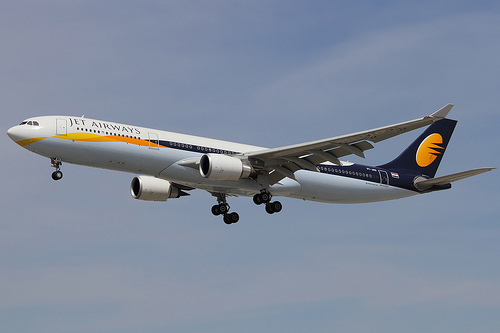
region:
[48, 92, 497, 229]
white, yellow and blue jet airplane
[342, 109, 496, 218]
blue and yellow tail fin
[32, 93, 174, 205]
jet airways airplane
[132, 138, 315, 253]
landing gear coming down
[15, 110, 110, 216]
cockpit of plane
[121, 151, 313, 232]
turbo jet engines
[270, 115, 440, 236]
wing landing gear opening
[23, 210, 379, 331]
gray, cloudy skies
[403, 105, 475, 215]
yellow sun logo on blue background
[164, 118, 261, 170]
plane's passenger windows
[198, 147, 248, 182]
the engine of a plane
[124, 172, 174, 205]
the engine of a plane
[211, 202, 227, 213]
the wheels of a plane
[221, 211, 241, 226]
the wheels of a plane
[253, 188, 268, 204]
the wheels of a plane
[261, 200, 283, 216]
the wheels of a plane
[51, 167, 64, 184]
the wheels of a plane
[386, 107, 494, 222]
the tail of a plane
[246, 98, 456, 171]
the wing of a plane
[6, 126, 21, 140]
the tip of a plane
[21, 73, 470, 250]
the plane is long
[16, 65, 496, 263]
the plane is white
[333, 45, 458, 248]
plane's tail is blue and yellow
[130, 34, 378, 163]
the sky is blue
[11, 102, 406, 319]
the engines are white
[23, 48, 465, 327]
the plane has wings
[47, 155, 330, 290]
the tires are black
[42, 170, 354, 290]
the plane has wheels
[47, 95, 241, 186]
the plane is Jet Airways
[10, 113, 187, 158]
the doors are closed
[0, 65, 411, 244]
jet airways airplane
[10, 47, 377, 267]
commercial airplane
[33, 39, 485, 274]
airplane flying in the sky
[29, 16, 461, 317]
cloudy day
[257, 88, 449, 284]
airplane having no issues flying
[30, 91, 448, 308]
yellow, orange, white, and blue airplane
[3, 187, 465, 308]
fluffy white clouds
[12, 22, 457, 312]
people being flown in an airplane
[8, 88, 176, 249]
nose of the airplane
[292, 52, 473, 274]
tail of the plane here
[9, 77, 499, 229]
a large Jet Airways aircraft flying in the sky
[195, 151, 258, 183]
a large jet engine on the wing of the aircraft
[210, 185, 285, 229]
the landing gear with two sets of four wheels under the aircraft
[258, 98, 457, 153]
a long silver wing extending from the aircraft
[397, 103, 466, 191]
the tail of the aircraft with a yellow logo on it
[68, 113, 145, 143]
the airline logo in blue on the front of the plane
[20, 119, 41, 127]
the cockpit windows on the very front of the plane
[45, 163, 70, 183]
the front tires of the landing gear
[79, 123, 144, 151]
a row of windows on the front of the aircraft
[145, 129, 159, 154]
a passenger door on the aircraft